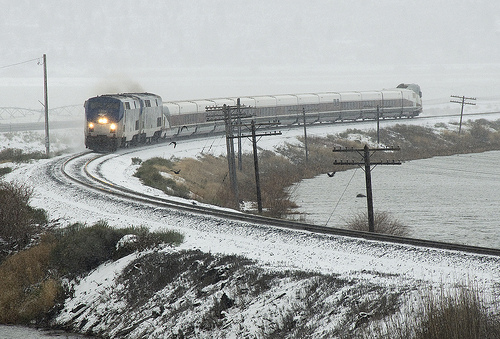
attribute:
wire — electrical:
[0, 53, 49, 85]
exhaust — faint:
[95, 71, 145, 94]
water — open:
[280, 147, 499, 253]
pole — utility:
[441, 89, 472, 139]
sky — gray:
[0, 3, 500, 118]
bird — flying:
[322, 169, 339, 179]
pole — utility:
[453, 82, 479, 135]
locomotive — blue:
[81, 87, 221, 152]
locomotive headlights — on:
[78, 115, 130, 144]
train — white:
[82, 80, 423, 152]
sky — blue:
[232, 22, 279, 40]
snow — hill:
[94, 233, 380, 327]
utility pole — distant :
[39, 51, 52, 160]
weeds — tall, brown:
[353, 276, 497, 336]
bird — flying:
[171, 169, 183, 179]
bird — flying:
[169, 135, 179, 147]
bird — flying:
[179, 120, 191, 134]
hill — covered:
[49, 241, 484, 334]